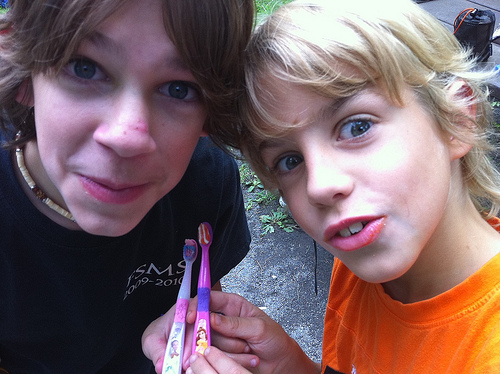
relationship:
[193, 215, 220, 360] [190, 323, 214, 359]
toothbrush with disney princess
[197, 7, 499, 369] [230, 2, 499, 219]
boy with blonde hair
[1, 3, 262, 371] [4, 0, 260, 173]
boy with brown hair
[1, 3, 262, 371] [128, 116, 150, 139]
boy has pimple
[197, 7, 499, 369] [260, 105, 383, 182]
boy has green eyes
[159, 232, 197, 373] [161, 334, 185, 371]
toothbrush with frog princess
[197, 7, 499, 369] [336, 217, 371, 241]
boy shows front teeth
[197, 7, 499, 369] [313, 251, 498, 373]
boy wears orange shirt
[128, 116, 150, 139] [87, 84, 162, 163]
spot on nose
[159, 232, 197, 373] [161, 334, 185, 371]
toothbrush has disney princes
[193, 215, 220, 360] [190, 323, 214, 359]
toothbrush has disney princess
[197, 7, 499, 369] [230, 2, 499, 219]
boy hair blonde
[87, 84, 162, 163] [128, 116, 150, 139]
nose has imperfection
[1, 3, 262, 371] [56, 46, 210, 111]
boy has blue eyes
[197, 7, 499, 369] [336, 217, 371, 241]
boy with buck teeth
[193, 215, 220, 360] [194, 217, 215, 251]
toothbrush has bristles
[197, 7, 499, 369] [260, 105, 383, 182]
child has eyes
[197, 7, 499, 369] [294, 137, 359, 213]
child has nose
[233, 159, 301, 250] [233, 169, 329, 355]
plants on ground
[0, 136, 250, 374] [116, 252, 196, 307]
tee shirt has white writing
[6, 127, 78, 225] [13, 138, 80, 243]
necklace on neck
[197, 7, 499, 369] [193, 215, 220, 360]
boy holds toothbrush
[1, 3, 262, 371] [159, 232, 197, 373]
boy holds toothbrush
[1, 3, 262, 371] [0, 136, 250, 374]
boy has black dress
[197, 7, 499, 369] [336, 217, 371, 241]
boy front teeth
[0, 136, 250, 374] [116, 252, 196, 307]
shirt has white writing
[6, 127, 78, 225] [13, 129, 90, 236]
necklace on neck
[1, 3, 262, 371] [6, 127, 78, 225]
boy wearing necklace